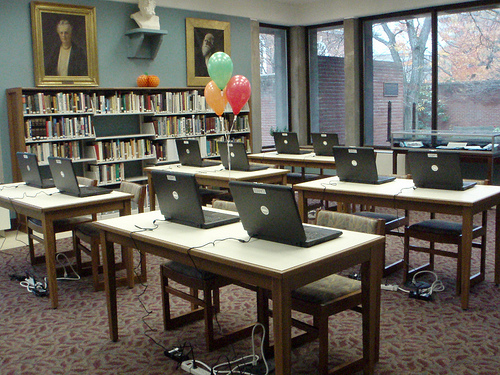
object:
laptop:
[148, 171, 242, 230]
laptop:
[229, 180, 345, 248]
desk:
[96, 203, 385, 375]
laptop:
[49, 157, 117, 197]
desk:
[0, 176, 135, 301]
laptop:
[18, 153, 57, 188]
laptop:
[335, 147, 399, 185]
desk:
[293, 172, 500, 310]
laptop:
[407, 147, 479, 191]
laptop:
[217, 141, 271, 172]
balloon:
[227, 74, 252, 115]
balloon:
[206, 51, 235, 92]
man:
[53, 19, 84, 76]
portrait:
[29, 1, 99, 90]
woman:
[199, 33, 215, 56]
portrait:
[184, 16, 226, 80]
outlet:
[176, 359, 226, 374]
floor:
[0, 201, 497, 372]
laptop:
[311, 133, 340, 157]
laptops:
[275, 131, 308, 155]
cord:
[251, 323, 268, 373]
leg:
[45, 217, 60, 310]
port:
[164, 346, 190, 362]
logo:
[259, 205, 270, 216]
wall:
[1, 1, 254, 87]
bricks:
[318, 64, 324, 67]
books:
[22, 94, 27, 114]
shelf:
[6, 86, 253, 190]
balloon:
[204, 80, 227, 117]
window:
[259, 25, 290, 149]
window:
[437, 10, 499, 144]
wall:
[316, 56, 405, 146]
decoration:
[135, 73, 159, 88]